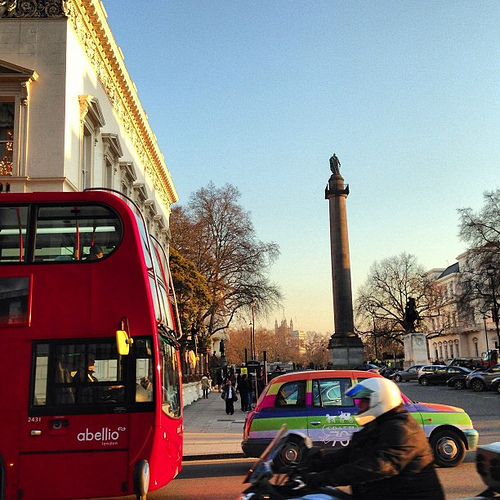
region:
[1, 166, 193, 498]
red bus on a street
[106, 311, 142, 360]
side rear view mirror on a vehicle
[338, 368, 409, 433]
helmet on a persons head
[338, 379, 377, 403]
visor on a helmet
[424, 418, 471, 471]
front wheel of a vehicle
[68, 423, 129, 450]
name on the side of a vehicle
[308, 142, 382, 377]
monument in a plaza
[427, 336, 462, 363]
windows on a building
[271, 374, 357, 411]
side windows on a vehicle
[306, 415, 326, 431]
handle on the door of a vehicle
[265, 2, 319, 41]
part of the sky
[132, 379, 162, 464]
edge of a bus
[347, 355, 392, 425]
part of a helmet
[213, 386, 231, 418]
part of a person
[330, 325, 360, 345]
part of a tower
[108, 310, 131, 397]
part of a side mirror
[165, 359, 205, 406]
part of a fence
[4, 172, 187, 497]
two story bus on road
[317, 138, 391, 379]
tall monument in plaza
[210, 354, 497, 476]
multi colored rainbow car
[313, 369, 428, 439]
motorcyclist wearing white helmet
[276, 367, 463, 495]
motorcyclist wearing brown jacket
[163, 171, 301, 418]
trees without leaves framing plaza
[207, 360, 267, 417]
people on grey sidewalk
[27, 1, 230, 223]
yellow border along top of building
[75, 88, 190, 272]
seven windows along side of building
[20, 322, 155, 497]
door on red bus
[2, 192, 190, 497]
front of a red double decker bus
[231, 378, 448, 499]
person on a motorbike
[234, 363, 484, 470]
brightly colored car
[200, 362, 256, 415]
people walking down the sidewalk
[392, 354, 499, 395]
cars parked in a row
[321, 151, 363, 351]
dark, round structure with a statue on top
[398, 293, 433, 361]
statue on a white pedestal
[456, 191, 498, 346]
tree without any leaves on it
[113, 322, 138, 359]
light shining on the side mirror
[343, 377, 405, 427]
white helmet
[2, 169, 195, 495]
red double decker bus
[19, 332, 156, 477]
white writing on red bus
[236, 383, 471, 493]
person on motorcycle in dark coat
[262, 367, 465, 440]
orange, yellow, pink, purple, green, white car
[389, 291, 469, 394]
statue on white base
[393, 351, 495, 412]
cars parked by statue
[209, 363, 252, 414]
people walking on sidewalk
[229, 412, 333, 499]
clear windshield on motorcycle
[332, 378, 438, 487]
white helmet on rider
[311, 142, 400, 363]
statue on tall tower